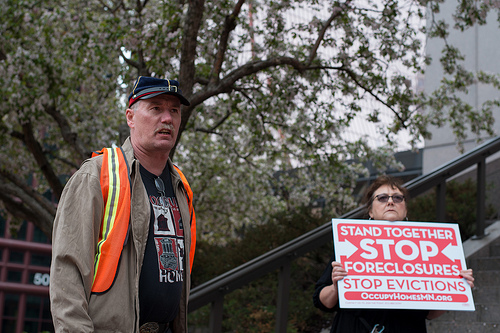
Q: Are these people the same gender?
A: No, they are both male and female.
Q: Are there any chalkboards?
A: No, there are no chalkboards.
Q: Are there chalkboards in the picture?
A: No, there are no chalkboards.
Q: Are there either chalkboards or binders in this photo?
A: No, there are no chalkboards or binders.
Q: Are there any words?
A: Yes, there are words.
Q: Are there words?
A: Yes, there are words.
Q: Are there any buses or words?
A: Yes, there are words.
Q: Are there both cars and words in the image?
A: No, there are words but no cars.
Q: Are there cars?
A: No, there are no cars.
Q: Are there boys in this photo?
A: No, there are no boys.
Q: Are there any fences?
A: No, there are no fences.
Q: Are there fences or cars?
A: No, there are no fences or cars.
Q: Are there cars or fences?
A: No, there are no fences or cars.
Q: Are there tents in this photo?
A: No, there are no tents.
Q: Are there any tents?
A: No, there are no tents.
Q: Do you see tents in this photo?
A: No, there are no tents.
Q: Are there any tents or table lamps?
A: No, there are no tents or table lamps.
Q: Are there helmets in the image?
A: No, there are no helmets.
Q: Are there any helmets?
A: No, there are no helmets.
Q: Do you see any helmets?
A: No, there are no helmets.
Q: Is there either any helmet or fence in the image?
A: No, there are no helmets or fences.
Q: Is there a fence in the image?
A: No, there are no fences.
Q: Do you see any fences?
A: No, there are no fences.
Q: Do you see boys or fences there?
A: No, there are no fences or boys.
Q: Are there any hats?
A: Yes, there is a hat.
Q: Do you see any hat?
A: Yes, there is a hat.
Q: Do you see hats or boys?
A: Yes, there is a hat.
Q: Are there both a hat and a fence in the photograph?
A: No, there is a hat but no fences.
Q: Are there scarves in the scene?
A: No, there are no scarves.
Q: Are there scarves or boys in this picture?
A: No, there are no scarves or boys.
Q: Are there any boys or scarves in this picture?
A: No, there are no scarves or boys.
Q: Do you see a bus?
A: No, there are no buses.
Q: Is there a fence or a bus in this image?
A: No, there are no buses or fences.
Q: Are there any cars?
A: No, there are no cars.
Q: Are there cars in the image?
A: No, there are no cars.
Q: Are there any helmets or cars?
A: No, there are no cars or helmets.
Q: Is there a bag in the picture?
A: No, there are no bags.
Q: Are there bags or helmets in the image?
A: No, there are no bags or helmets.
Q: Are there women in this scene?
A: Yes, there is a woman.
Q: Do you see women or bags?
A: Yes, there is a woman.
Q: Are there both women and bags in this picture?
A: No, there is a woman but no bags.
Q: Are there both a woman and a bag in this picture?
A: No, there is a woman but no bags.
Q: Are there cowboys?
A: No, there are no cowboys.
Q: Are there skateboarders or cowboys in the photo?
A: No, there are no cowboys or skateboarders.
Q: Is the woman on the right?
A: Yes, the woman is on the right of the image.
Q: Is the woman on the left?
A: No, the woman is on the right of the image.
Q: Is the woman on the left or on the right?
A: The woman is on the right of the image.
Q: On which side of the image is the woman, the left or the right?
A: The woman is on the right of the image.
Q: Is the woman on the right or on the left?
A: The woman is on the right of the image.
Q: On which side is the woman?
A: The woman is on the right of the image.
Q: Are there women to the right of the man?
A: Yes, there is a woman to the right of the man.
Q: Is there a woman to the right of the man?
A: Yes, there is a woman to the right of the man.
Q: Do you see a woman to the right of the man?
A: Yes, there is a woman to the right of the man.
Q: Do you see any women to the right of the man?
A: Yes, there is a woman to the right of the man.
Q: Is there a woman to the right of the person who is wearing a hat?
A: Yes, there is a woman to the right of the man.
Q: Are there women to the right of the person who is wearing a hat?
A: Yes, there is a woman to the right of the man.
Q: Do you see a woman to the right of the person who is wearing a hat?
A: Yes, there is a woman to the right of the man.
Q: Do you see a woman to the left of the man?
A: No, the woman is to the right of the man.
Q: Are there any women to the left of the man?
A: No, the woman is to the right of the man.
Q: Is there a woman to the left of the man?
A: No, the woman is to the right of the man.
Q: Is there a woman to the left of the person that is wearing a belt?
A: No, the woman is to the right of the man.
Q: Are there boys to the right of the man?
A: No, there is a woman to the right of the man.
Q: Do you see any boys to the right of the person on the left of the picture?
A: No, there is a woman to the right of the man.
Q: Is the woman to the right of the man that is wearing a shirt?
A: Yes, the woman is to the right of the man.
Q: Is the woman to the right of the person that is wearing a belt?
A: Yes, the woman is to the right of the man.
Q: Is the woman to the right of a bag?
A: No, the woman is to the right of the man.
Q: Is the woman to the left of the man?
A: No, the woman is to the right of the man.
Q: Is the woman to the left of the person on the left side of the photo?
A: No, the woman is to the right of the man.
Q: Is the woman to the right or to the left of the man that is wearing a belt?
A: The woman is to the right of the man.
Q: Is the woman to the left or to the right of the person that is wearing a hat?
A: The woman is to the right of the man.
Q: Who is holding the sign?
A: The woman is holding the sign.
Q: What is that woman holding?
A: The woman is holding the sign.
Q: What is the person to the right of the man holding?
A: The woman is holding the sign.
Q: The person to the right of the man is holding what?
A: The woman is holding the sign.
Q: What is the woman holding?
A: The woman is holding the sign.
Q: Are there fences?
A: No, there are no fences.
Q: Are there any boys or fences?
A: No, there are no fences or boys.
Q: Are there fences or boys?
A: No, there are no fences or boys.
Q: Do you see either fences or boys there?
A: No, there are no fences or boys.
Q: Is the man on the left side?
A: Yes, the man is on the left of the image.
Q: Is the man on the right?
A: No, the man is on the left of the image.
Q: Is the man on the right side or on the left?
A: The man is on the left of the image.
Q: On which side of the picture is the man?
A: The man is on the left of the image.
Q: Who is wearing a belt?
A: The man is wearing a belt.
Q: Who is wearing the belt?
A: The man is wearing a belt.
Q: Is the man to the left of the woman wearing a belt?
A: Yes, the man is wearing a belt.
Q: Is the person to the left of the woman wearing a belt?
A: Yes, the man is wearing a belt.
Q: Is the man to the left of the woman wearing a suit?
A: No, the man is wearing a belt.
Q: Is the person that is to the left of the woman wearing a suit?
A: No, the man is wearing a belt.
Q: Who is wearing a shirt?
A: The man is wearing a shirt.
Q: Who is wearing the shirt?
A: The man is wearing a shirt.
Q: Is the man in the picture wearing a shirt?
A: Yes, the man is wearing a shirt.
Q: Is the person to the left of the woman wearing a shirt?
A: Yes, the man is wearing a shirt.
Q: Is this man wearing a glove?
A: No, the man is wearing a shirt.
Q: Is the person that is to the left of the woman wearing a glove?
A: No, the man is wearing a shirt.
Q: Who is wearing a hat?
A: The man is wearing a hat.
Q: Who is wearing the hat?
A: The man is wearing a hat.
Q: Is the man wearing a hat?
A: Yes, the man is wearing a hat.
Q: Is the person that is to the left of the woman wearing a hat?
A: Yes, the man is wearing a hat.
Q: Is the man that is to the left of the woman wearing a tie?
A: No, the man is wearing a hat.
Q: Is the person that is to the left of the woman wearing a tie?
A: No, the man is wearing a hat.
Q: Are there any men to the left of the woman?
A: Yes, there is a man to the left of the woman.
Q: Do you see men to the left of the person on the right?
A: Yes, there is a man to the left of the woman.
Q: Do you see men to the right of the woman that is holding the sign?
A: No, the man is to the left of the woman.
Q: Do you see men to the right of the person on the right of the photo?
A: No, the man is to the left of the woman.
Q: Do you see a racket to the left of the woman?
A: No, there is a man to the left of the woman.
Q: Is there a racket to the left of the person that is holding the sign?
A: No, there is a man to the left of the woman.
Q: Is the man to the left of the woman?
A: Yes, the man is to the left of the woman.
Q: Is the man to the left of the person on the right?
A: Yes, the man is to the left of the woman.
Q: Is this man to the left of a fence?
A: No, the man is to the left of the woman.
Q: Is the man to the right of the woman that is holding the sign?
A: No, the man is to the left of the woman.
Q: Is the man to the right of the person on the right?
A: No, the man is to the left of the woman.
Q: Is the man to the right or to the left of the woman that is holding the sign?
A: The man is to the left of the woman.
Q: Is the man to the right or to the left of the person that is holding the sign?
A: The man is to the left of the woman.